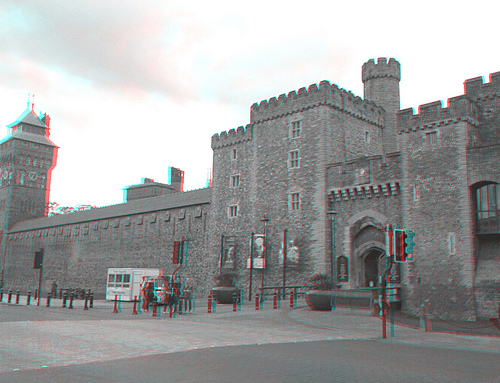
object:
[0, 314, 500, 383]
foreground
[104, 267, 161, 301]
truck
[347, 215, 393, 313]
door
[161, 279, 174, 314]
people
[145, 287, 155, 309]
black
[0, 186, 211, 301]
wall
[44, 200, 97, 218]
trees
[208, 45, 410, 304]
prison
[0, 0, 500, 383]
photo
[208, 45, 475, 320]
building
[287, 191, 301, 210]
windows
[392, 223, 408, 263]
traffic light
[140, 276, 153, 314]
people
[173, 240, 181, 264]
traffic lights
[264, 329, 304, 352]
part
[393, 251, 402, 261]
part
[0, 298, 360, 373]
walking path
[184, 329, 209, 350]
part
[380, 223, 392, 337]
post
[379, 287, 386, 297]
part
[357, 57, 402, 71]
tip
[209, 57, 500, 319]
castle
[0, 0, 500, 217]
sky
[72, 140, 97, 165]
part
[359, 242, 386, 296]
entrance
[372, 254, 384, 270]
section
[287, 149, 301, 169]
window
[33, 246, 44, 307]
post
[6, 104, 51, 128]
roof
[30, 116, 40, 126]
part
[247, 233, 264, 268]
sign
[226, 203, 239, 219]
windows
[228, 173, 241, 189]
windows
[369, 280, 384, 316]
man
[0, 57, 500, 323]
building